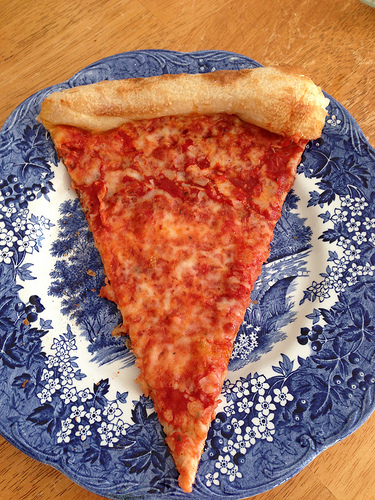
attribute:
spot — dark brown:
[205, 70, 251, 87]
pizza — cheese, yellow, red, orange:
[40, 73, 331, 392]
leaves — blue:
[319, 213, 345, 248]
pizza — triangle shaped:
[80, 137, 285, 464]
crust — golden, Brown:
[34, 68, 325, 145]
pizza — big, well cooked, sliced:
[38, 65, 330, 495]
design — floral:
[4, 46, 374, 487]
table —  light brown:
[0, 0, 367, 48]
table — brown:
[324, 457, 366, 496]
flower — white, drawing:
[46, 342, 128, 450]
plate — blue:
[249, 218, 363, 435]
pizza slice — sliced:
[48, 63, 338, 494]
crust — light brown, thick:
[42, 72, 321, 134]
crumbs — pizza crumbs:
[19, 271, 127, 395]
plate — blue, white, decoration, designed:
[0, 47, 371, 497]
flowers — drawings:
[237, 374, 287, 434]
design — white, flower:
[12, 245, 124, 393]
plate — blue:
[54, 62, 371, 418]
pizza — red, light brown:
[45, 118, 331, 284]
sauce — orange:
[47, 113, 309, 493]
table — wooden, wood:
[1, 0, 373, 499]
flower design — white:
[6, 111, 374, 486]